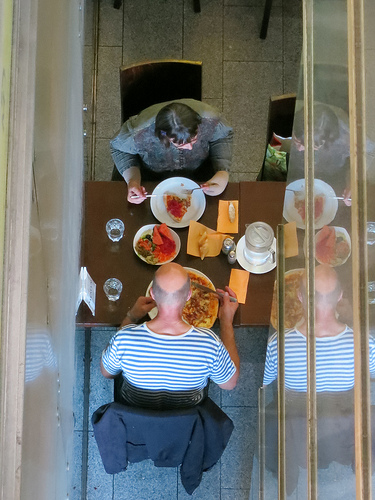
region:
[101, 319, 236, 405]
a blue and white striped shirt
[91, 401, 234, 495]
a black jacket hanging over chair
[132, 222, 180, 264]
a large white bowl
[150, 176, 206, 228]
a large white plate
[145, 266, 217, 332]
a large white plate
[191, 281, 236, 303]
a silver knife utensil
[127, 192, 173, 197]
a silver knife utensil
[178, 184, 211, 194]
a silver fork utensil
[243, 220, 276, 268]
a clear pitcher of water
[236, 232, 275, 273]
a large white plate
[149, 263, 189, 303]
the bright bald head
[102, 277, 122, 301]
the clear drinking glass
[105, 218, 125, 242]
the clear drinking glass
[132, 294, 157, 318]
the hand of the person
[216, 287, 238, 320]
the hand of the person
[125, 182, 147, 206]
the hand of the person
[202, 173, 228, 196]
the hand of the person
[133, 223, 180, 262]
the white plate with food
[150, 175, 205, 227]
the white plate with food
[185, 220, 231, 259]
the orange napkin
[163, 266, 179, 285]
the guy is bald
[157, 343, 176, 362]
the shirt has stripes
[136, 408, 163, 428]
the coat is over the chair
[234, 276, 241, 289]
the napkin is orange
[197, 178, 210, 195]
she is holding the fork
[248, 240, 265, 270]
the water container is on the plate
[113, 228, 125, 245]
the glass is on the table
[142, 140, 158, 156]
the shirt is gray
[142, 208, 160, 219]
the plate is on the table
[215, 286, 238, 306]
he is holding the knife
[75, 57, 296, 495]
older couple sitting and eating meal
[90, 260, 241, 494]
partially bald man eating food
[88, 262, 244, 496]
man in blue and white stripe shirt sitting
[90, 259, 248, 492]
Man sitting holding a knife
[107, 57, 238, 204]
woman in grey sitting on wooden chair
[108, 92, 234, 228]
woman eating a slice of pizza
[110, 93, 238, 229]
woman eating with fork and knife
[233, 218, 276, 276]
pitcher on plate with clear liquid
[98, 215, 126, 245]
glass on table with clear liquid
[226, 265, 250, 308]
orange colored paper on table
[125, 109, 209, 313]
people sitting at a table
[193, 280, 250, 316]
a man holding a knife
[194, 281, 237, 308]
a man cutting a pizza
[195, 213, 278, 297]
orange napkins sitting on the table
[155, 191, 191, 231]
a slice of pizza on a plate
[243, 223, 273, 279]
a pitcher of water sitting on a plate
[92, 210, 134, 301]
glasses sitting on a table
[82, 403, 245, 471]
a jacket draped behind a chair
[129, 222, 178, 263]
food sitting on a plate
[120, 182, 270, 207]
a person holding silver utensils